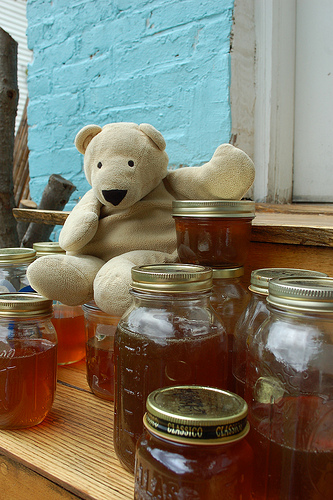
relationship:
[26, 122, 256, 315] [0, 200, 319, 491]
teddy bear with jars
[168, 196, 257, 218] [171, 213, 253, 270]
cap on jar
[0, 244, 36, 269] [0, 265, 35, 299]
cap on jar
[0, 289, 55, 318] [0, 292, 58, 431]
cap on glass jar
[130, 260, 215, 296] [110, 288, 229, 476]
cap on jar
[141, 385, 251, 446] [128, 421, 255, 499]
cap on jar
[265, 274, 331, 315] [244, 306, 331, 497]
cap on jar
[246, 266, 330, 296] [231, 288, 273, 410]
cap on jar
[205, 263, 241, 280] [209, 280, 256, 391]
cap on jar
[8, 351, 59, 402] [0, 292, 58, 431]
liquid in glass jar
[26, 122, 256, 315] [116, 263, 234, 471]
teddy bear sitting on honey jar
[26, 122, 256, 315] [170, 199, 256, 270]
teddy bear sitting on jar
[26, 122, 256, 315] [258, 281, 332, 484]
teddy bear sitting on honey jar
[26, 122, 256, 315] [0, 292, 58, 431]
teddy bear sitting on glass jar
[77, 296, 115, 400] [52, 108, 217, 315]
jar under stuffed animal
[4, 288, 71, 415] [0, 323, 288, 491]
glass jar on table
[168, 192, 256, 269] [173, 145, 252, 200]
jar under arm